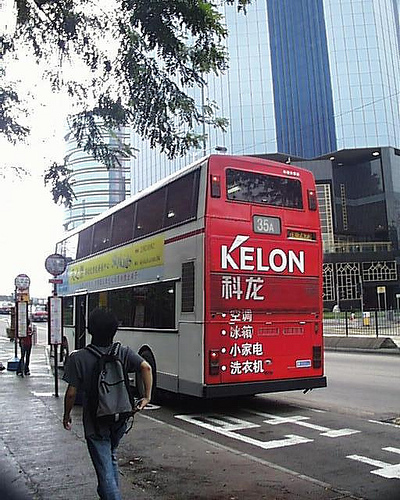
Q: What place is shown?
A: It is a road.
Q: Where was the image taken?
A: It was taken at the road.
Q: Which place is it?
A: It is a road.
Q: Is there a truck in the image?
A: No, there are no trucks.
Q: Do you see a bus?
A: Yes, there is a bus.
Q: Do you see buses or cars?
A: Yes, there is a bus.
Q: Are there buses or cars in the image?
A: Yes, there is a bus.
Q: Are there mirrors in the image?
A: No, there are no mirrors.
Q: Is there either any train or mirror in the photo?
A: No, there are no mirrors or trains.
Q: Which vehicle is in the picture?
A: The vehicle is a bus.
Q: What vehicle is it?
A: The vehicle is a bus.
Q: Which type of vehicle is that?
A: This is a bus.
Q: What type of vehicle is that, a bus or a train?
A: This is a bus.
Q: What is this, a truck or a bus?
A: This is a bus.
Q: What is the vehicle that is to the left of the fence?
A: The vehicle is a bus.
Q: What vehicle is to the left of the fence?
A: The vehicle is a bus.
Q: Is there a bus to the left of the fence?
A: Yes, there is a bus to the left of the fence.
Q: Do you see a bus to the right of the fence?
A: No, the bus is to the left of the fence.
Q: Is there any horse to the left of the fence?
A: No, there is a bus to the left of the fence.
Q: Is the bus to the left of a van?
A: No, the bus is to the left of the fence.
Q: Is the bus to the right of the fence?
A: No, the bus is to the left of the fence.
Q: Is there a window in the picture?
A: Yes, there is a window.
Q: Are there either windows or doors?
A: Yes, there is a window.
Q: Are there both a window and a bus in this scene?
A: Yes, there are both a window and a bus.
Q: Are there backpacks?
A: Yes, there is a backpack.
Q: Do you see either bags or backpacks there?
A: Yes, there is a backpack.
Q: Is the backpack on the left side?
A: Yes, the backpack is on the left of the image.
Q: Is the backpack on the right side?
A: No, the backpack is on the left of the image.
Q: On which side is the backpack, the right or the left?
A: The backpack is on the left of the image.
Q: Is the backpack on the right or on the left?
A: The backpack is on the left of the image.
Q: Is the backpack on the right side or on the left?
A: The backpack is on the left of the image.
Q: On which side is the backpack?
A: The backpack is on the left of the image.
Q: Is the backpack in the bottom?
A: Yes, the backpack is in the bottom of the image.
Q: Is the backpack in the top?
A: No, the backpack is in the bottom of the image.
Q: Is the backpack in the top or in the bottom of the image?
A: The backpack is in the bottom of the image.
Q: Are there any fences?
A: Yes, there is a fence.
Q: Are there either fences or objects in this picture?
A: Yes, there is a fence.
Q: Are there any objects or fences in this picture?
A: Yes, there is a fence.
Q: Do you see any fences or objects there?
A: Yes, there is a fence.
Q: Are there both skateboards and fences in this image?
A: No, there is a fence but no skateboards.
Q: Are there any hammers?
A: No, there are no hammers.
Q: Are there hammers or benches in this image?
A: No, there are no hammers or benches.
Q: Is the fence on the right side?
A: Yes, the fence is on the right of the image.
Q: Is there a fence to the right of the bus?
A: Yes, there is a fence to the right of the bus.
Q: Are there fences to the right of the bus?
A: Yes, there is a fence to the right of the bus.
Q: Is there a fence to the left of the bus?
A: No, the fence is to the right of the bus.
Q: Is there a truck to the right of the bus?
A: No, there is a fence to the right of the bus.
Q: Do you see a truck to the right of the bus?
A: No, there is a fence to the right of the bus.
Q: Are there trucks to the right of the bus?
A: No, there is a fence to the right of the bus.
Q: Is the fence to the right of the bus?
A: Yes, the fence is to the right of the bus.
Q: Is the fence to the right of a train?
A: No, the fence is to the right of the bus.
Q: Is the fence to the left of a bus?
A: No, the fence is to the right of a bus.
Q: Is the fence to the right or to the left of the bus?
A: The fence is to the right of the bus.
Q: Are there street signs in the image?
A: Yes, there is a street sign.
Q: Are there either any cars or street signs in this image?
A: Yes, there is a street sign.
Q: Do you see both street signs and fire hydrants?
A: No, there is a street sign but no fire hydrants.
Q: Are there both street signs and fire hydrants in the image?
A: No, there is a street sign but no fire hydrants.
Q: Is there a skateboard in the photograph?
A: No, there are no skateboards.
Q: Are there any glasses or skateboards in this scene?
A: No, there are no skateboards or glasses.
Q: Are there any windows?
A: Yes, there is a window.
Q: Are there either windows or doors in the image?
A: Yes, there is a window.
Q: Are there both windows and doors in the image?
A: Yes, there are both a window and a door.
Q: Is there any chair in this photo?
A: No, there are no chairs.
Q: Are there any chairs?
A: No, there are no chairs.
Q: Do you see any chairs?
A: No, there are no chairs.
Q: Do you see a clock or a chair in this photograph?
A: No, there are no chairs or clocks.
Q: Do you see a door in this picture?
A: Yes, there is a door.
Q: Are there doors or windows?
A: Yes, there is a door.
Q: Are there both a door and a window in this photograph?
A: Yes, there are both a door and a window.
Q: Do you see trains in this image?
A: No, there are no trains.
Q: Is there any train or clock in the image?
A: No, there are no trains or clocks.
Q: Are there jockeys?
A: No, there are no jockeys.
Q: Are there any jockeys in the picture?
A: No, there are no jockeys.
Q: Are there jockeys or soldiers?
A: No, there are no jockeys or soldiers.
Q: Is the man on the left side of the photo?
A: Yes, the man is on the left of the image.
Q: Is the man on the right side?
A: No, the man is on the left of the image.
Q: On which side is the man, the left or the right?
A: The man is on the left of the image.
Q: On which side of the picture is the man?
A: The man is on the left of the image.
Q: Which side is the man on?
A: The man is on the left of the image.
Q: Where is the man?
A: The man is on the sidewalk.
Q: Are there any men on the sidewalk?
A: Yes, there is a man on the sidewalk.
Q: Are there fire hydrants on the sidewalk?
A: No, there is a man on the sidewalk.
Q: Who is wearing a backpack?
A: The man is wearing a backpack.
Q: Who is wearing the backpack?
A: The man is wearing a backpack.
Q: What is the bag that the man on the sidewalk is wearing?
A: The bag is a backpack.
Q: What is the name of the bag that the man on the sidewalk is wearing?
A: The bag is a backpack.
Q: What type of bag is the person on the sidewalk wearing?
A: The man is wearing a backpack.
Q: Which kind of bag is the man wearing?
A: The man is wearing a backpack.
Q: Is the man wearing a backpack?
A: Yes, the man is wearing a backpack.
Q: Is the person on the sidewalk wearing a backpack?
A: Yes, the man is wearing a backpack.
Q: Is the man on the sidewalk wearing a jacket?
A: No, the man is wearing a backpack.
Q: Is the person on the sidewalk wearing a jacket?
A: No, the man is wearing a backpack.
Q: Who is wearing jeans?
A: The man is wearing jeans.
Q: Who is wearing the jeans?
A: The man is wearing jeans.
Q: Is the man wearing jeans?
A: Yes, the man is wearing jeans.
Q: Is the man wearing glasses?
A: No, the man is wearing jeans.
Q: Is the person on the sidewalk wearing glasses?
A: No, the man is wearing jeans.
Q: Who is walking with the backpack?
A: The man is walking with the backpack.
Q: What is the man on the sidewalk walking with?
A: The man is walking with a backpack.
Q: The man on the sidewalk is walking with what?
A: The man is walking with a backpack.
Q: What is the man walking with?
A: The man is walking with a backpack.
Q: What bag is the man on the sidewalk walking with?
A: The man is walking with a backpack.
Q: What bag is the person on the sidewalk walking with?
A: The man is walking with a backpack.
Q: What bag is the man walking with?
A: The man is walking with a backpack.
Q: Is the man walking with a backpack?
A: Yes, the man is walking with a backpack.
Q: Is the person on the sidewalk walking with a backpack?
A: Yes, the man is walking with a backpack.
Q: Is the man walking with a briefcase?
A: No, the man is walking with a backpack.